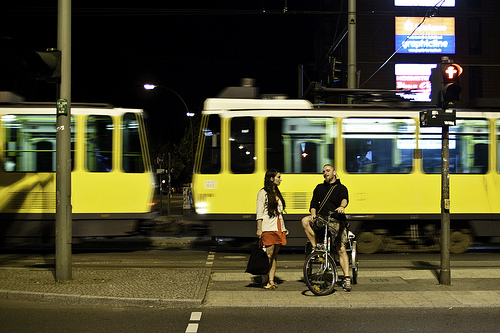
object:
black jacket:
[308, 177, 350, 220]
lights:
[281, 118, 492, 134]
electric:
[441, 62, 465, 82]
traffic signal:
[428, 58, 467, 107]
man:
[299, 163, 355, 293]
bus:
[180, 74, 500, 261]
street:
[4, 226, 495, 331]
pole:
[51, 0, 75, 287]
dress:
[255, 187, 289, 248]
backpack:
[243, 236, 273, 276]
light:
[325, 55, 343, 85]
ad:
[391, 61, 441, 102]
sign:
[55, 96, 69, 117]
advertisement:
[390, 13, 460, 56]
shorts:
[307, 209, 350, 248]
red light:
[442, 62, 466, 82]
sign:
[391, 58, 449, 105]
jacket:
[254, 188, 289, 234]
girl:
[243, 165, 293, 292]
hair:
[258, 167, 290, 220]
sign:
[391, 16, 457, 56]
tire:
[300, 249, 339, 297]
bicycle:
[297, 208, 365, 298]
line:
[181, 309, 204, 333]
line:
[202, 247, 217, 270]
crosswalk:
[180, 239, 500, 333]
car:
[0, 88, 162, 254]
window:
[339, 113, 419, 176]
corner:
[0, 60, 497, 332]